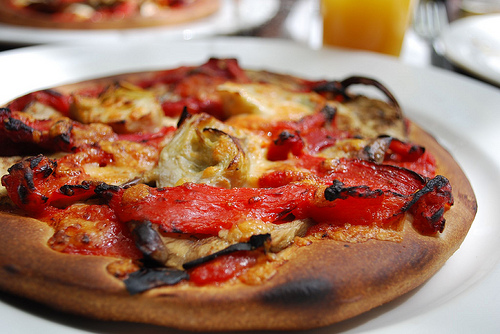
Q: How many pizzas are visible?
A: Two.